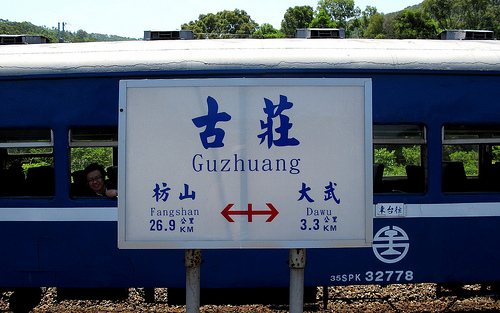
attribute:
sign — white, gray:
[116, 75, 390, 304]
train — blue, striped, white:
[1, 25, 498, 288]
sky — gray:
[10, 1, 398, 18]